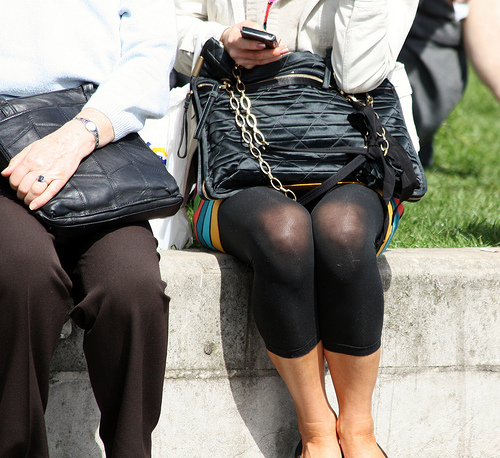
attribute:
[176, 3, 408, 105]
shirt — white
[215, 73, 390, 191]
chain — gold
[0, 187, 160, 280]
lap — woman's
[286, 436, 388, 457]
shoes — slip-on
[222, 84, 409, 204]
strap — chain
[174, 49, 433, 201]
bag — black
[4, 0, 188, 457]
woman — holding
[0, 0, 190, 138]
shirt — white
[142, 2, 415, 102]
shirt — white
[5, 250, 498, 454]
wall — stone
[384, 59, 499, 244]
grass — green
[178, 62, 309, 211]
purse — black 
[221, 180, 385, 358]
leggings — black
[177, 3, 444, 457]
person — sitting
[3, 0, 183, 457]
person — sitting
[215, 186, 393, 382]
leggings — black